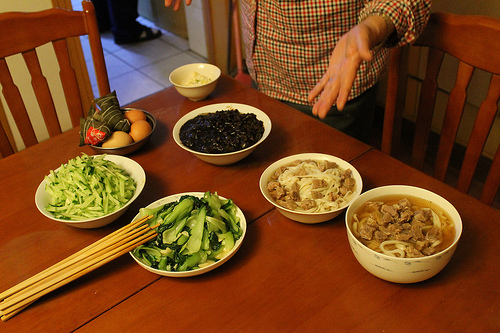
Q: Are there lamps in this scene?
A: No, there are no lamps.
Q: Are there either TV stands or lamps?
A: No, there are no lamps or TV stands.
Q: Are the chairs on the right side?
A: Yes, the chairs are on the right of the image.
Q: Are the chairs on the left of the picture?
A: No, the chairs are on the right of the image.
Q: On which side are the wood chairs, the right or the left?
A: The chairs are on the right of the image.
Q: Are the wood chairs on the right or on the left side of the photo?
A: The chairs are on the right of the image.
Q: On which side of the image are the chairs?
A: The chairs are on the right of the image.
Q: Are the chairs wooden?
A: Yes, the chairs are wooden.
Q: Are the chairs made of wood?
A: Yes, the chairs are made of wood.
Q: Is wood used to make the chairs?
A: Yes, the chairs are made of wood.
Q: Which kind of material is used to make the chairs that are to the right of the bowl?
A: The chairs are made of wood.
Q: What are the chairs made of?
A: The chairs are made of wood.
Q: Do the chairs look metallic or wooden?
A: The chairs are wooden.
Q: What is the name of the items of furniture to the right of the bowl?
A: The pieces of furniture are chairs.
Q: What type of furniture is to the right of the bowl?
A: The pieces of furniture are chairs.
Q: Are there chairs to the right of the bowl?
A: Yes, there are chairs to the right of the bowl.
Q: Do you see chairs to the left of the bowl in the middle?
A: No, the chairs are to the right of the bowl.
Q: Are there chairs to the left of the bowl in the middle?
A: No, the chairs are to the right of the bowl.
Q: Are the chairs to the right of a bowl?
A: Yes, the chairs are to the right of a bowl.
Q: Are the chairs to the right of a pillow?
A: No, the chairs are to the right of a bowl.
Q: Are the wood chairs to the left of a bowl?
A: No, the chairs are to the right of a bowl.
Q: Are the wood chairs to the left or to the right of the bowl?
A: The chairs are to the right of the bowl.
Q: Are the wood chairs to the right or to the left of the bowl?
A: The chairs are to the right of the bowl.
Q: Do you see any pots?
A: No, there are no pots.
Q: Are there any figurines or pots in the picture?
A: No, there are no pots or figurines.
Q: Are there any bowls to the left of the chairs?
A: Yes, there is a bowl to the left of the chairs.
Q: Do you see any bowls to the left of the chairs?
A: Yes, there is a bowl to the left of the chairs.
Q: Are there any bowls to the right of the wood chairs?
A: No, the bowl is to the left of the chairs.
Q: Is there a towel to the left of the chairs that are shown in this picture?
A: No, there is a bowl to the left of the chairs.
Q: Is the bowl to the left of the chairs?
A: Yes, the bowl is to the left of the chairs.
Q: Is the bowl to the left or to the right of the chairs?
A: The bowl is to the left of the chairs.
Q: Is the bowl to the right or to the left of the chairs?
A: The bowl is to the left of the chairs.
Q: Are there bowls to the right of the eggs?
A: Yes, there is a bowl to the right of the eggs.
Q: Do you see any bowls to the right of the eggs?
A: Yes, there is a bowl to the right of the eggs.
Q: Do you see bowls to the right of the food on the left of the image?
A: Yes, there is a bowl to the right of the eggs.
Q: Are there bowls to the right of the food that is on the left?
A: Yes, there is a bowl to the right of the eggs.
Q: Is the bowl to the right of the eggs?
A: Yes, the bowl is to the right of the eggs.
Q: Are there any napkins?
A: No, there are no napkins.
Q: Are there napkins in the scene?
A: No, there are no napkins.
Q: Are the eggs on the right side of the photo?
A: No, the eggs are on the left of the image.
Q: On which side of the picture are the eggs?
A: The eggs are on the left of the image.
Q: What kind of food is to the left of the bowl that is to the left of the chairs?
A: The food is eggs.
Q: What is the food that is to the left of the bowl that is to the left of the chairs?
A: The food is eggs.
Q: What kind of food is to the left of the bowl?
A: The food is eggs.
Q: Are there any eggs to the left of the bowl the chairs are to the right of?
A: Yes, there are eggs to the left of the bowl.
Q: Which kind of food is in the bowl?
A: The food is eggs.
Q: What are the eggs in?
A: The eggs are in the bowl.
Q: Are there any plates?
A: Yes, there is a plate.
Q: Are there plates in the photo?
A: Yes, there is a plate.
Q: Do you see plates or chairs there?
A: Yes, there is a plate.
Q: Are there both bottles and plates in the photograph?
A: No, there is a plate but no bottles.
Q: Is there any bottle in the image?
A: No, there are no bottles.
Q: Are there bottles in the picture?
A: No, there are no bottles.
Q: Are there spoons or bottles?
A: No, there are no bottles or spoons.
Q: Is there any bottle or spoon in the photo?
A: No, there are no bottles or spoons.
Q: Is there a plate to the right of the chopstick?
A: Yes, there is a plate to the right of the chopstick.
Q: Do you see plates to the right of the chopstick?
A: Yes, there is a plate to the right of the chopstick.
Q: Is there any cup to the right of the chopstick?
A: No, there is a plate to the right of the chopstick.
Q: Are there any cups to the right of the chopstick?
A: No, there is a plate to the right of the chopstick.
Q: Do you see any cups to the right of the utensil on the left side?
A: No, there is a plate to the right of the chopstick.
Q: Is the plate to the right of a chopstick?
A: Yes, the plate is to the right of a chopstick.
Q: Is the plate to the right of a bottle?
A: No, the plate is to the right of a chopstick.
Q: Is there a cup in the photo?
A: No, there are no cups.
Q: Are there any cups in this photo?
A: No, there are no cups.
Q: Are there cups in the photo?
A: No, there are no cups.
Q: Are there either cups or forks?
A: No, there are no cups or forks.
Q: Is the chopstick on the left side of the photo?
A: Yes, the chopstick is on the left of the image.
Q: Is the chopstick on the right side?
A: No, the chopstick is on the left of the image.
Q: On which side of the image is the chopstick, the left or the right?
A: The chopstick is on the left of the image.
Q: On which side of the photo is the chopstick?
A: The chopstick is on the left of the image.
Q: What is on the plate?
A: The chopstick is on the plate.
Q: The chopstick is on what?
A: The chopstick is on the plate.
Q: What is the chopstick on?
A: The chopstick is on the plate.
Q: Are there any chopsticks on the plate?
A: Yes, there is a chopstick on the plate.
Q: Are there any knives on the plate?
A: No, there is a chopstick on the plate.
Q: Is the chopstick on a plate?
A: Yes, the chopstick is on a plate.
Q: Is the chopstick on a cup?
A: No, the chopstick is on a plate.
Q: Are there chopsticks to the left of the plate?
A: Yes, there is a chopstick to the left of the plate.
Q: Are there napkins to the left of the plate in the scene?
A: No, there is a chopstick to the left of the plate.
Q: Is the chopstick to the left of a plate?
A: Yes, the chopstick is to the left of a plate.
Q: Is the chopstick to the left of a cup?
A: No, the chopstick is to the left of a plate.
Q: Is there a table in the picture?
A: Yes, there is a table.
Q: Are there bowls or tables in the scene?
A: Yes, there is a table.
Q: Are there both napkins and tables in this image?
A: No, there is a table but no napkins.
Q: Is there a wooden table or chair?
A: Yes, there is a wood table.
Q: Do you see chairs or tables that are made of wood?
A: Yes, the table is made of wood.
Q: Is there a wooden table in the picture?
A: Yes, there is a wood table.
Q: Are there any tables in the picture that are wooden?
A: Yes, there is a table that is wooden.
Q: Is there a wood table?
A: Yes, there is a table that is made of wood.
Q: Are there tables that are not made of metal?
A: Yes, there is a table that is made of wood.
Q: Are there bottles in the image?
A: No, there are no bottles.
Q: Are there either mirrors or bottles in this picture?
A: No, there are no bottles or mirrors.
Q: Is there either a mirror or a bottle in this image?
A: No, there are no bottles or mirrors.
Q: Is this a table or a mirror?
A: This is a table.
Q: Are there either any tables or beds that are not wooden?
A: No, there is a table but it is wooden.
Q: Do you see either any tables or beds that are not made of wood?
A: No, there is a table but it is made of wood.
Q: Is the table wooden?
A: Yes, the table is wooden.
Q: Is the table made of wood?
A: Yes, the table is made of wood.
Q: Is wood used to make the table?
A: Yes, the table is made of wood.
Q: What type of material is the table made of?
A: The table is made of wood.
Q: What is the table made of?
A: The table is made of wood.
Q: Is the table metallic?
A: No, the table is wooden.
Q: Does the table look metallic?
A: No, the table is wooden.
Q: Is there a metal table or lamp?
A: No, there is a table but it is wooden.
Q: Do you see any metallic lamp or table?
A: No, there is a table but it is wooden.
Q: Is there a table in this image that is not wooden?
A: No, there is a table but it is wooden.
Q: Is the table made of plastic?
A: No, the table is made of wood.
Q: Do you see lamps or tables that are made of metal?
A: No, there is a table but it is made of wood.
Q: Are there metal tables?
A: No, there is a table but it is made of wood.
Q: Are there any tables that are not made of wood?
A: No, there is a table but it is made of wood.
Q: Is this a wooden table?
A: Yes, this is a wooden table.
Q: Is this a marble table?
A: No, this is a wooden table.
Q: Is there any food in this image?
A: Yes, there is food.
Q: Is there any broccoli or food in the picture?
A: Yes, there is food.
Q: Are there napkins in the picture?
A: No, there are no napkins.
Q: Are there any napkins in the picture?
A: No, there are no napkins.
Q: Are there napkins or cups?
A: No, there are no napkins or cups.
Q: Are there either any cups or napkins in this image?
A: No, there are no napkins or cups.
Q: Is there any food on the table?
A: Yes, there is food on the table.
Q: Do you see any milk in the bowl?
A: No, there is food in the bowl.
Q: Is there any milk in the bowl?
A: No, there is food in the bowl.